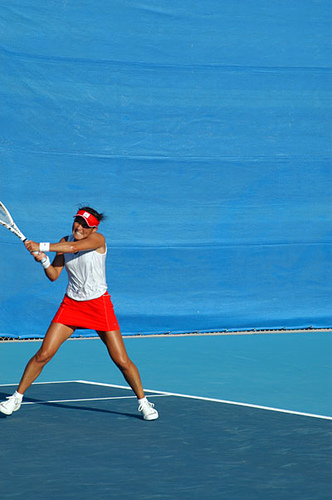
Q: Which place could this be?
A: It is a field.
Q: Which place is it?
A: It is a field.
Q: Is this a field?
A: Yes, it is a field.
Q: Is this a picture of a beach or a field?
A: It is showing a field.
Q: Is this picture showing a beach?
A: No, the picture is showing a field.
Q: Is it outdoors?
A: Yes, it is outdoors.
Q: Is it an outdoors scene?
A: Yes, it is outdoors.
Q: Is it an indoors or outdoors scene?
A: It is outdoors.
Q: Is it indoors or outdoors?
A: It is outdoors.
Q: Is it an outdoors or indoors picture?
A: It is outdoors.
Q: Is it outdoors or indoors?
A: It is outdoors.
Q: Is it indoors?
A: No, it is outdoors.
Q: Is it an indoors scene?
A: No, it is outdoors.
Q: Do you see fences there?
A: No, there are no fences.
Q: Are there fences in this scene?
A: No, there are no fences.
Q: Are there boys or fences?
A: No, there are no fences or boys.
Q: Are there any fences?
A: No, there are no fences.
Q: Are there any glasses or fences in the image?
A: No, there are no fences or glasses.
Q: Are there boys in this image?
A: No, there are no boys.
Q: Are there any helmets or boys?
A: No, there are no boys or helmets.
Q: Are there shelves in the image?
A: No, there are no shelves.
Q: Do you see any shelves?
A: No, there are no shelves.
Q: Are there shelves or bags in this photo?
A: No, there are no shelves or bags.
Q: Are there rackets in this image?
A: Yes, there is a racket.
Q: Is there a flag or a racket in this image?
A: Yes, there is a racket.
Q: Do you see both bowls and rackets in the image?
A: No, there is a racket but no bowls.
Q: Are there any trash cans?
A: No, there are no trash cans.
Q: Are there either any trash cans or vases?
A: No, there are no trash cans or vases.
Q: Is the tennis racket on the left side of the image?
A: Yes, the tennis racket is on the left of the image.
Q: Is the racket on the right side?
A: No, the racket is on the left of the image.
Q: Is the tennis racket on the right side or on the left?
A: The tennis racket is on the left of the image.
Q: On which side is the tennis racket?
A: The tennis racket is on the left of the image.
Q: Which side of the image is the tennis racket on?
A: The tennis racket is on the left of the image.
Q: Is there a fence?
A: No, there are no fences.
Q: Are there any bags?
A: No, there are no bags.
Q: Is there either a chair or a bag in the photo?
A: No, there are no bags or chairs.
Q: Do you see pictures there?
A: No, there are no pictures.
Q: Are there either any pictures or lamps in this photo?
A: No, there are no pictures or lamps.